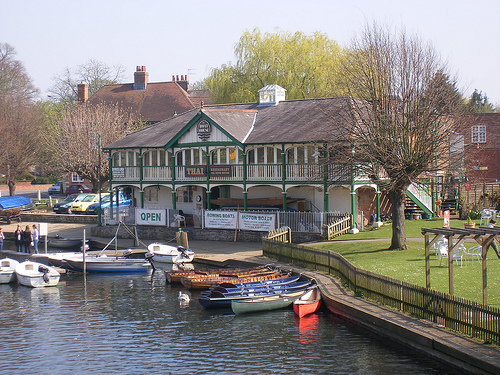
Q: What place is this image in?
A: It is at the sidewalk.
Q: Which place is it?
A: It is a sidewalk.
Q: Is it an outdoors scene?
A: Yes, it is outdoors.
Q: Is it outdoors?
A: Yes, it is outdoors.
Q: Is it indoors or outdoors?
A: It is outdoors.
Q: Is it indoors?
A: No, it is outdoors.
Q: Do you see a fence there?
A: Yes, there is a fence.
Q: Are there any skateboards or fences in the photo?
A: Yes, there is a fence.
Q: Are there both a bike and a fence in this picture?
A: No, there is a fence but no bikes.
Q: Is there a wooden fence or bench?
A: Yes, there is a wood fence.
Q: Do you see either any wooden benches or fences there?
A: Yes, there is a wood fence.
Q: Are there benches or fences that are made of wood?
A: Yes, the fence is made of wood.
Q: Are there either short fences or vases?
A: Yes, there is a short fence.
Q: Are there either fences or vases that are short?
A: Yes, the fence is short.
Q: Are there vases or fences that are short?
A: Yes, the fence is short.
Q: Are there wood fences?
A: Yes, there is a fence that is made of wood.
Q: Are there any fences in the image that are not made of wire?
A: Yes, there is a fence that is made of wood.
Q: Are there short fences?
A: Yes, there is a short fence.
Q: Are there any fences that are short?
A: Yes, there is a fence that is short.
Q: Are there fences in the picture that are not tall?
A: Yes, there is a short fence.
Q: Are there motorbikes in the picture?
A: No, there are no motorbikes.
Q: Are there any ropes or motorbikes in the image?
A: No, there are no motorbikes or ropes.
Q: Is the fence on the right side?
A: Yes, the fence is on the right of the image.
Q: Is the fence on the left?
A: No, the fence is on the right of the image.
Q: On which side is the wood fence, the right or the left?
A: The fence is on the right of the image.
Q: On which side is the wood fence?
A: The fence is on the right of the image.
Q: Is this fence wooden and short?
A: Yes, the fence is wooden and short.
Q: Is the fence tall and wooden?
A: No, the fence is wooden but short.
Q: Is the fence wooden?
A: Yes, the fence is wooden.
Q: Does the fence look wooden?
A: Yes, the fence is wooden.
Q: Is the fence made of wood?
A: Yes, the fence is made of wood.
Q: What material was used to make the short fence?
A: The fence is made of wood.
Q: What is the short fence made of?
A: The fence is made of wood.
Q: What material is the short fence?
A: The fence is made of wood.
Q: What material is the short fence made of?
A: The fence is made of wood.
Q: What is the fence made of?
A: The fence is made of wood.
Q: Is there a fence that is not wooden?
A: No, there is a fence but it is wooden.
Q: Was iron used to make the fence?
A: No, the fence is made of wood.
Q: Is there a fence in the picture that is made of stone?
A: No, there is a fence but it is made of wood.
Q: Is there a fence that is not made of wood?
A: No, there is a fence but it is made of wood.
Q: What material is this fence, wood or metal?
A: The fence is made of wood.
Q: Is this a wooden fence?
A: Yes, this is a wooden fence.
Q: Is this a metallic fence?
A: No, this is a wooden fence.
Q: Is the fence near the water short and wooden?
A: Yes, the fence is short and wooden.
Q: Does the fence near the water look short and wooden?
A: Yes, the fence is short and wooden.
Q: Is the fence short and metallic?
A: No, the fence is short but wooden.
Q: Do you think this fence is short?
A: Yes, the fence is short.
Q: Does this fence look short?
A: Yes, the fence is short.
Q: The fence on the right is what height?
A: The fence is short.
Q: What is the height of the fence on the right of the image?
A: The fence is short.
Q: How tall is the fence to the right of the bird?
A: The fence is short.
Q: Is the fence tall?
A: No, the fence is short.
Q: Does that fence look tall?
A: No, the fence is short.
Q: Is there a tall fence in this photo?
A: No, there is a fence but it is short.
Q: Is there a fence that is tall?
A: No, there is a fence but it is short.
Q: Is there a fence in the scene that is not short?
A: No, there is a fence but it is short.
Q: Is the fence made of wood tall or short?
A: The fence is short.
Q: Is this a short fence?
A: Yes, this is a short fence.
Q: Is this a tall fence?
A: No, this is a short fence.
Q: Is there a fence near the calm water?
A: Yes, there is a fence near the water.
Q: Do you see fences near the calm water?
A: Yes, there is a fence near the water.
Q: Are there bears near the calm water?
A: No, there is a fence near the water.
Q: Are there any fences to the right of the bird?
A: Yes, there is a fence to the right of the bird.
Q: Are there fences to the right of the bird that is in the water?
A: Yes, there is a fence to the right of the bird.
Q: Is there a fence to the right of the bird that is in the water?
A: Yes, there is a fence to the right of the bird.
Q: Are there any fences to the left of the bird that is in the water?
A: No, the fence is to the right of the bird.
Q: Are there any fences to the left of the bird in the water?
A: No, the fence is to the right of the bird.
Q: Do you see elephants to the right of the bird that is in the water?
A: No, there is a fence to the right of the bird.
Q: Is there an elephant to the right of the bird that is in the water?
A: No, there is a fence to the right of the bird.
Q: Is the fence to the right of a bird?
A: Yes, the fence is to the right of a bird.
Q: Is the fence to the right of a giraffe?
A: No, the fence is to the right of a bird.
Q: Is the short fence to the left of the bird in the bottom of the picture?
A: No, the fence is to the right of the bird.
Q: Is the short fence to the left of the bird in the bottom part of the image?
A: No, the fence is to the right of the bird.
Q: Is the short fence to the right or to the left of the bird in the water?
A: The fence is to the right of the bird.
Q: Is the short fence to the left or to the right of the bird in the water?
A: The fence is to the right of the bird.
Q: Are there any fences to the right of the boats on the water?
A: Yes, there is a fence to the right of the boats.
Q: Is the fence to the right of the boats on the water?
A: Yes, the fence is to the right of the boats.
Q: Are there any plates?
A: No, there are no plates.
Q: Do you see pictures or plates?
A: No, there are no plates or pictures.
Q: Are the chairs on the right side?
A: Yes, the chairs are on the right of the image.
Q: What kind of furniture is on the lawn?
A: The pieces of furniture are chairs.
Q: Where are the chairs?
A: The chairs are on the lawn.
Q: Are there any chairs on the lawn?
A: Yes, there are chairs on the lawn.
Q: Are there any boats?
A: Yes, there is a boat.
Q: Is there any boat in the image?
A: Yes, there is a boat.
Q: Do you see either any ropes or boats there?
A: Yes, there is a boat.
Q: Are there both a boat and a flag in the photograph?
A: No, there is a boat but no flags.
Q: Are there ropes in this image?
A: No, there are no ropes.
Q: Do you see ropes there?
A: No, there are no ropes.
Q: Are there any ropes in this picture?
A: No, there are no ropes.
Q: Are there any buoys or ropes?
A: No, there are no ropes or buoys.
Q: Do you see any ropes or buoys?
A: No, there are no ropes or buoys.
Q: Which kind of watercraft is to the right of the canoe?
A: The watercraft is a boat.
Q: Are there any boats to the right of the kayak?
A: Yes, there is a boat to the right of the kayak.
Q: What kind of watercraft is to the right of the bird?
A: The watercraft is a boat.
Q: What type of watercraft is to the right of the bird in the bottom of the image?
A: The watercraft is a boat.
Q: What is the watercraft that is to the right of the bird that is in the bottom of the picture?
A: The watercraft is a boat.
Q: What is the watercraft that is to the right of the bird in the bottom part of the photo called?
A: The watercraft is a boat.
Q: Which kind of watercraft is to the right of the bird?
A: The watercraft is a boat.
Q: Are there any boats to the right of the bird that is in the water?
A: Yes, there is a boat to the right of the bird.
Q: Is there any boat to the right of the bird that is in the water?
A: Yes, there is a boat to the right of the bird.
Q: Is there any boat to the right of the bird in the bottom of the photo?
A: Yes, there is a boat to the right of the bird.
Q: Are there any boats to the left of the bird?
A: No, the boat is to the right of the bird.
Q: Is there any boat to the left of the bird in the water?
A: No, the boat is to the right of the bird.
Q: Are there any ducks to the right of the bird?
A: No, there is a boat to the right of the bird.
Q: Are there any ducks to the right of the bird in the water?
A: No, there is a boat to the right of the bird.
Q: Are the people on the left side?
A: Yes, the people are on the left of the image.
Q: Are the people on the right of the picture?
A: No, the people are on the left of the image.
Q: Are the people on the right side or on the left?
A: The people are on the left of the image.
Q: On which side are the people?
A: The people are on the left of the image.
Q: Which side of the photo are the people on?
A: The people are on the left of the image.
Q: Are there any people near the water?
A: Yes, there are people near the water.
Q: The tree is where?
A: The tree is on the lawn.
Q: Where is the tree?
A: The tree is on the lawn.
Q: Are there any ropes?
A: No, there are no ropes.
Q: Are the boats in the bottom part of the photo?
A: Yes, the boats are in the bottom of the image.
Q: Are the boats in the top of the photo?
A: No, the boats are in the bottom of the image.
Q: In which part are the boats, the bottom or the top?
A: The boats are in the bottom of the image.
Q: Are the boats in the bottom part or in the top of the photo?
A: The boats are in the bottom of the image.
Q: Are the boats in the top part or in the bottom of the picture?
A: The boats are in the bottom of the image.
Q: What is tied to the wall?
A: The boats are tied to the wall.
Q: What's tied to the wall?
A: The boats are tied to the wall.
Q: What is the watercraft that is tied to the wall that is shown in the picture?
A: The watercraft is boats.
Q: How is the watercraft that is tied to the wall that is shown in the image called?
A: The watercraft is boats.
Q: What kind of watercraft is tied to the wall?
A: The watercraft is boats.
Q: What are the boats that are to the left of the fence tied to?
A: The boats are tied to the wall.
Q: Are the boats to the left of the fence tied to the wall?
A: Yes, the boats are tied to the wall.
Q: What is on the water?
A: The boats are on the water.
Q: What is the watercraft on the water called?
A: The watercraft is boats.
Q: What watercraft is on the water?
A: The watercraft is boats.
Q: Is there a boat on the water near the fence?
A: Yes, there are boats on the water.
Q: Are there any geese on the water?
A: No, there are boats on the water.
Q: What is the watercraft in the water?
A: The watercraft is boats.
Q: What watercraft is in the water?
A: The watercraft is boats.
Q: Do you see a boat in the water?
A: Yes, there are boats in the water.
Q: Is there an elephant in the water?
A: No, there are boats in the water.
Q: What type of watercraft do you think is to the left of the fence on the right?
A: The watercraft is boats.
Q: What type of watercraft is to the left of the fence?
A: The watercraft is boats.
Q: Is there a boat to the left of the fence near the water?
A: Yes, there are boats to the left of the fence.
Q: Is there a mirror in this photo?
A: No, there are no mirrors.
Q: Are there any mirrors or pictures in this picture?
A: No, there are no mirrors or pictures.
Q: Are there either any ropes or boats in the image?
A: Yes, there is a boat.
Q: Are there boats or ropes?
A: Yes, there is a boat.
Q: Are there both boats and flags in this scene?
A: No, there is a boat but no flags.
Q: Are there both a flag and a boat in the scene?
A: No, there is a boat but no flags.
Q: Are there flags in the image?
A: No, there are no flags.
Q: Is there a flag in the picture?
A: No, there are no flags.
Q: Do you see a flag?
A: No, there are no flags.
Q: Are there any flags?
A: No, there are no flags.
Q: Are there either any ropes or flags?
A: No, there are no flags or ropes.